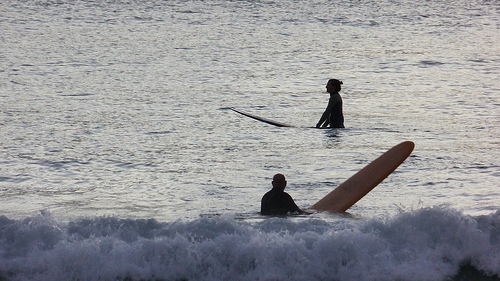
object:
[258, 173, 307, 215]
man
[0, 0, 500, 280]
water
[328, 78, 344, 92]
hair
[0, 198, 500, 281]
froth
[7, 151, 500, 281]
wave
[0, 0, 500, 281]
ocean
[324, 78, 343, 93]
head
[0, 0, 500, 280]
photo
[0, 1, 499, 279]
outdoors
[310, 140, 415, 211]
surf board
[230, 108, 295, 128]
surf board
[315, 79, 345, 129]
girl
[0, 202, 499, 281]
spray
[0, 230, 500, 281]
shore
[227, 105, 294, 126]
board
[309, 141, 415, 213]
board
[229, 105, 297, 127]
front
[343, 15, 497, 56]
light